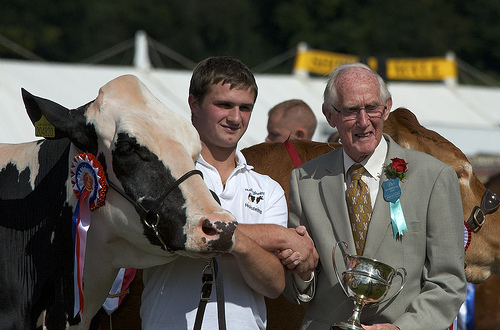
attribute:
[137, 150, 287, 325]
shirt — white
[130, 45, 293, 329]
shirt — white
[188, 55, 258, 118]
hair — short, brown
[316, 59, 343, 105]
hair — gray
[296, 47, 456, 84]
banner — long, yellow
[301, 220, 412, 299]
trophy — small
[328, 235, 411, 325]
trophy — silver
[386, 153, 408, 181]
rose — red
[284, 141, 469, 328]
coat — gray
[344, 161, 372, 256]
tie — brown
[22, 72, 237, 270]
head — white, black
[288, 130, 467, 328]
suit — gray